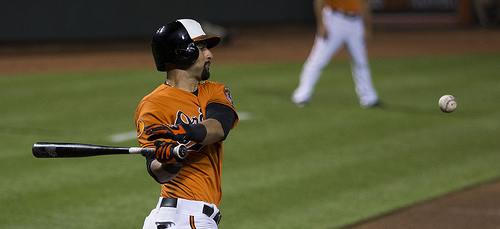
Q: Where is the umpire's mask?
A: On his face.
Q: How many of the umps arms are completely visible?
A: One.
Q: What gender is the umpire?
A: Male.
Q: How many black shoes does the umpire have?
A: Two.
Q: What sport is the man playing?
A: Baseball.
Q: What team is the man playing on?
A: The Orioles.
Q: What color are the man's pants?
A: White.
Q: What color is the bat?
A: Black.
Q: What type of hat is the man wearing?
A: A batting helmet.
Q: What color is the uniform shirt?
A: Orange.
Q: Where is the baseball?
A: In the air.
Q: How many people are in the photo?
A: Two.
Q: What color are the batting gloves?
A: Black and orange.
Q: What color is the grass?
A: Green.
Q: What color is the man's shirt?
A: Orange.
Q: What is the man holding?
A: A baseball bat.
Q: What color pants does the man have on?
A: White.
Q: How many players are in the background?
A: One.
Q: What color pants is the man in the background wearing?
A: White.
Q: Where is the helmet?
A: On the man's head.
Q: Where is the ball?
A: In front of the man.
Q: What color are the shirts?
A: Orange.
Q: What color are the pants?
A: White.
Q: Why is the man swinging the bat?
A: To hit the baseball.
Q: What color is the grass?
A: Green.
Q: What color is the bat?
A: Black.